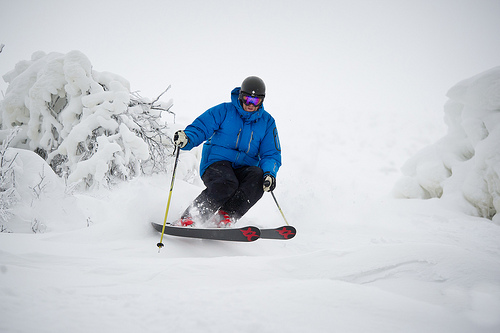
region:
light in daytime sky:
[0, 2, 498, 168]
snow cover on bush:
[2, 48, 180, 187]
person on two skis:
[152, 75, 297, 246]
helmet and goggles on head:
[239, 75, 267, 112]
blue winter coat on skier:
[184, 85, 282, 179]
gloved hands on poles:
[155, 127, 290, 247]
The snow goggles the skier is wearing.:
[237, 95, 261, 106]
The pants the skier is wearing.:
[192, 160, 266, 227]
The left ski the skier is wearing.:
[156, 220, 263, 245]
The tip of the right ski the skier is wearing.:
[250, 226, 300, 237]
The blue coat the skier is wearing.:
[182, 100, 282, 174]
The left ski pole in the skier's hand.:
[162, 140, 179, 238]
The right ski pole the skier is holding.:
[266, 183, 296, 228]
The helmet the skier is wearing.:
[236, 73, 264, 91]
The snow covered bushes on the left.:
[10, 48, 174, 205]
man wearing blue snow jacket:
[176, 83, 284, 181]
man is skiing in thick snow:
[167, 72, 287, 228]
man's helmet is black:
[235, 72, 266, 99]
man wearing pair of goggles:
[237, 88, 263, 106]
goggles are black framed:
[237, 90, 262, 107]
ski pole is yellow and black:
[152, 141, 180, 247]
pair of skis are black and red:
[150, 215, 297, 243]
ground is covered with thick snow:
[0, 193, 498, 328]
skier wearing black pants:
[179, 159, 264, 229]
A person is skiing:
[143, 68, 303, 256]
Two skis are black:
[145, 215, 297, 245]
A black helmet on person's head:
[232, 67, 267, 112]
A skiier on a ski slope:
[0, 42, 495, 327]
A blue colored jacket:
[175, 80, 286, 180]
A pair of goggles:
[235, 85, 265, 110]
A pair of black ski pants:
[170, 155, 267, 230]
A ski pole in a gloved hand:
[146, 121, 187, 251]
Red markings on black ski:
[235, 217, 261, 243]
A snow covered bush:
[381, 58, 496, 230]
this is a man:
[122, 34, 339, 271]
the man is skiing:
[34, 32, 445, 321]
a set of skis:
[117, 182, 312, 249]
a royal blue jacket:
[160, 82, 288, 184]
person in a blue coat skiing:
[153, 76, 297, 249]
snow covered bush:
[1, 51, 174, 184]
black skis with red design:
[151, 220, 296, 242]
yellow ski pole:
[157, 136, 180, 252]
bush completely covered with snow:
[392, 66, 498, 223]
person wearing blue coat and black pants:
[172, 75, 281, 227]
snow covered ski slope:
[1, 172, 498, 330]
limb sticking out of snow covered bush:
[129, 85, 178, 115]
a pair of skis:
[151, 198, 296, 251]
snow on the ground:
[0, 165, 498, 327]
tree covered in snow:
[1, 42, 179, 217]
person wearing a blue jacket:
[162, 90, 288, 181]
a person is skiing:
[129, 65, 310, 254]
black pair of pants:
[184, 150, 276, 230]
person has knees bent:
[172, 160, 276, 233]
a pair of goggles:
[241, 90, 265, 107]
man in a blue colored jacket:
[145, 71, 307, 264]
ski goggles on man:
[240, 92, 262, 102]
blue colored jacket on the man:
[177, 105, 284, 170]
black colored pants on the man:
[171, 161, 271, 216]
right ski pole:
[145, 130, 186, 245]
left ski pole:
[256, 170, 291, 225]